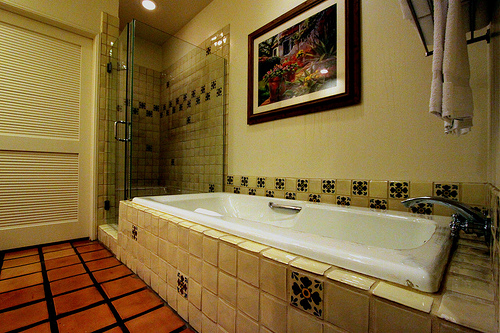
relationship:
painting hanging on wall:
[243, 0, 361, 128] [210, 0, 486, 217]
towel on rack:
[398, 0, 476, 137] [411, 0, 498, 55]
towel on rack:
[398, 0, 434, 41] [411, 0, 498, 55]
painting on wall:
[241, 15, 353, 111] [210, 0, 486, 217]